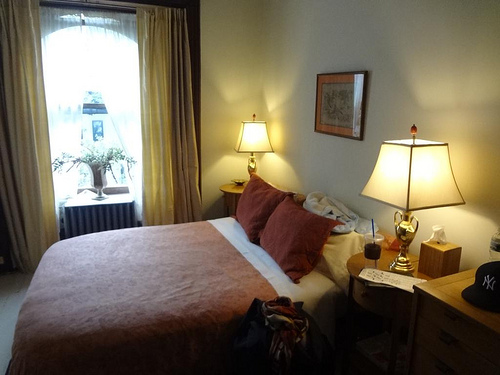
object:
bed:
[3, 173, 401, 374]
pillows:
[256, 194, 335, 274]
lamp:
[359, 124, 466, 275]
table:
[347, 233, 464, 375]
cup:
[360, 243, 381, 260]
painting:
[309, 67, 371, 143]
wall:
[253, 0, 500, 271]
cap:
[461, 263, 498, 315]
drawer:
[413, 259, 499, 372]